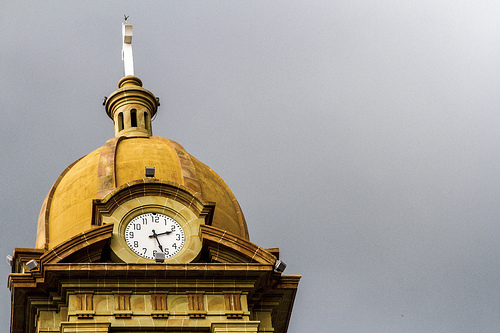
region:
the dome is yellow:
[19, 16, 301, 329]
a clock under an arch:
[97, 181, 276, 325]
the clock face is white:
[37, 143, 267, 313]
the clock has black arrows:
[67, 141, 233, 284]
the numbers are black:
[71, 140, 244, 282]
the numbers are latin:
[56, 170, 266, 308]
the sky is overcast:
[285, 107, 375, 162]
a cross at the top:
[89, 9, 274, 229]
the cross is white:
[96, 16, 242, 182]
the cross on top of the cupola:
[51, 10, 248, 191]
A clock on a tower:
[83, 194, 203, 279]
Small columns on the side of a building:
[70, 281, 254, 325]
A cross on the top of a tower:
[86, 4, 156, 92]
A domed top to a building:
[28, 121, 288, 262]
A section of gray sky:
[291, 38, 414, 198]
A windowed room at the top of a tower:
[99, 90, 171, 142]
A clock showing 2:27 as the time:
[108, 197, 204, 274]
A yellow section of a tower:
[58, 180, 85, 228]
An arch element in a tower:
[43, 230, 108, 281]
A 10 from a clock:
[132, 220, 144, 232]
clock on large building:
[118, 203, 186, 255]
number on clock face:
[151, 213, 163, 225]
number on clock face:
[160, 217, 172, 226]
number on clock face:
[173, 233, 181, 243]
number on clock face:
[166, 237, 180, 248]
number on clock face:
[163, 245, 170, 253]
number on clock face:
[133, 222, 144, 232]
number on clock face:
[129, 241, 143, 247]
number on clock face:
[139, 248, 149, 255]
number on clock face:
[146, 247, 154, 254]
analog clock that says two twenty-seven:
[107, 189, 208, 269]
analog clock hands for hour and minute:
[147, 223, 177, 254]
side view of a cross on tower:
[88, 5, 168, 143]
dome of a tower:
[27, 133, 261, 232]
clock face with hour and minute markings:
[118, 201, 192, 258]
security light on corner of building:
[263, 253, 296, 284]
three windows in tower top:
[97, 70, 172, 147]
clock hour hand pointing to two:
[144, 223, 187, 243]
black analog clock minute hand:
[146, 228, 168, 255]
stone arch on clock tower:
[32, 221, 292, 283]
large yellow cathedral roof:
[4, 17, 310, 331]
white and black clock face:
[105, 196, 198, 268]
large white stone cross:
[110, 17, 145, 78]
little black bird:
[116, 9, 133, 27]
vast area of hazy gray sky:
[2, 0, 498, 331]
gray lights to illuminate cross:
[1, 251, 49, 277]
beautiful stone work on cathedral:
[19, 284, 259, 329]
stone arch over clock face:
[85, 173, 217, 227]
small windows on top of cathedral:
[93, 100, 172, 145]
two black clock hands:
[147, 224, 173, 251]